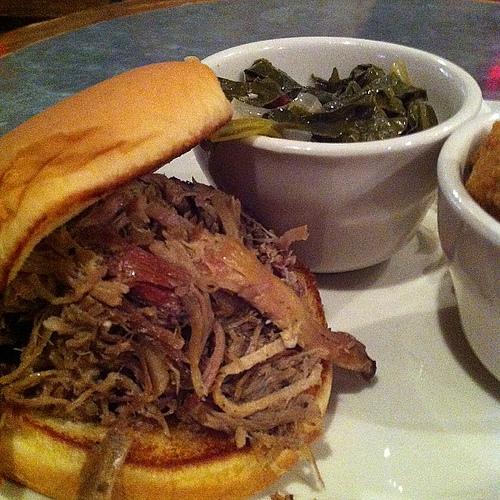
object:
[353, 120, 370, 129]
vegetable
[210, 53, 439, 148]
greens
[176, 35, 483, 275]
cup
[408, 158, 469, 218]
ground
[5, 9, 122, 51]
edge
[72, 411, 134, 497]
meat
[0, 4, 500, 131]
blue table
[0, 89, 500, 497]
plate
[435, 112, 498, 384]
bowl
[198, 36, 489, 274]
bowl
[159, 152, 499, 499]
surface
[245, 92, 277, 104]
vegetable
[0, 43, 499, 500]
food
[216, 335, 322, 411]
meat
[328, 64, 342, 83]
green vegatable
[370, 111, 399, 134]
vegetable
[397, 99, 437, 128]
spinach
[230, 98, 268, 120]
onion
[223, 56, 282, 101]
spinach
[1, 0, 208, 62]
wooden edge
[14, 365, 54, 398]
meat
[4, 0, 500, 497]
indoors scene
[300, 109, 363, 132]
spinach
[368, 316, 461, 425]
shadow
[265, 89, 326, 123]
kale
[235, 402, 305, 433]
pulled pork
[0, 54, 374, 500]
bread roll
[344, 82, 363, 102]
vegetable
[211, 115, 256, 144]
vegetable